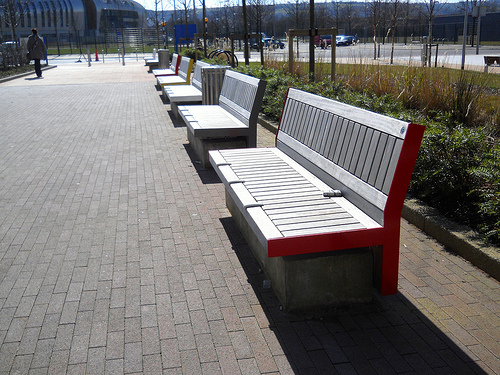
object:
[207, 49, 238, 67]
rack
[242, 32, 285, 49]
car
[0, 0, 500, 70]
background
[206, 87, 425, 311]
bench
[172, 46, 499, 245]
bushes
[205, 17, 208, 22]
spotlight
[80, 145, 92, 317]
bad semtence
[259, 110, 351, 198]
"bed sentence"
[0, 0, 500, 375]
outside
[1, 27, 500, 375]
pathway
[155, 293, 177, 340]
bricks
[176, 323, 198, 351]
bricks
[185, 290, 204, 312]
bricks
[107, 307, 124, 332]
bricks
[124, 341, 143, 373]
bricks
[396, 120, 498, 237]
green plants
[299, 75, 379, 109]
green plants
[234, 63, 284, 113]
green plants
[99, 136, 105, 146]
brick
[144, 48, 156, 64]
bench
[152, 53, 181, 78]
bench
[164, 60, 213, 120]
bench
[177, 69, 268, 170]
bench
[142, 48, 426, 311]
row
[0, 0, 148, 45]
building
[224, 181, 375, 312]
block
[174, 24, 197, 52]
blue sign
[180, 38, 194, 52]
pole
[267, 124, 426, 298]
paint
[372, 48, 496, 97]
flowers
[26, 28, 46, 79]
person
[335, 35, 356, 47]
cars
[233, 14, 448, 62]
street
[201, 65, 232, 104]
can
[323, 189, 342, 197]
lock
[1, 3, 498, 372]
bad statement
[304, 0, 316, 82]
tree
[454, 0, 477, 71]
tree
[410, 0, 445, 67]
tree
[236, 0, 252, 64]
tree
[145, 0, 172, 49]
tree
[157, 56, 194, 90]
bench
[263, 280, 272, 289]
debris